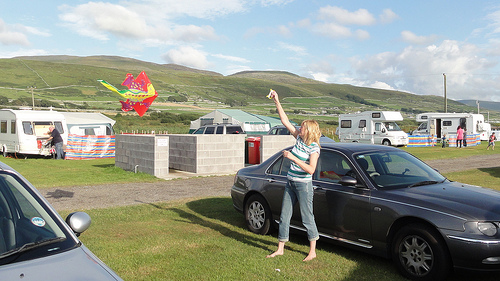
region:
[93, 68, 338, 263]
A WOMAN FLYING A KITE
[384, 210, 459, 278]
A FRONT CARS TIRE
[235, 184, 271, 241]
A REAR CARS TIRE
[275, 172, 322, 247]
A PAIR OF BLUE JEANS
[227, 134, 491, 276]
A BLACK CAR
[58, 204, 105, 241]
A SIDE VIEW MIRROR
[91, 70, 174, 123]
A KITE FLYING IN THE AIR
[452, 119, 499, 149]
TWO PEOPLE IN THE BACKGROUND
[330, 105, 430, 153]
A WHITE CAMPER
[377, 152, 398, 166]
A REAR VIEW MIRROR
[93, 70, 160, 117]
A multicolored flying kite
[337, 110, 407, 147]
A white drivable camper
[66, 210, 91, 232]
Side view mirror of a silver car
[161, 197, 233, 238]
Shadows on the grassy ground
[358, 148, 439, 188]
Windshield of a car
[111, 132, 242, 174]
A partial concrete block wall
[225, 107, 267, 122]
A green roof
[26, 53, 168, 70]
Grassy green mountain top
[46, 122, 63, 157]
Person in a black shirt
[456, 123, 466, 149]
Lady in a pink shirt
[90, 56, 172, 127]
a kite in the air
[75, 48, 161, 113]
a kite flying low in the air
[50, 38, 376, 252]
a woman flying a kite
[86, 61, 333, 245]
a woman holding a kite string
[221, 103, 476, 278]
a woman standing next to car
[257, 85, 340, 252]
a woman with blonde hair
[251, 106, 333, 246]
a woman wearing a striped shirt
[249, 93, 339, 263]
a woman wearing pants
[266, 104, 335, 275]
a woman wearing jeans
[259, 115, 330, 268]
a woman wearing blue jeans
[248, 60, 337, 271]
bare foot blind woman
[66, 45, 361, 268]
bare foot blonde woman flying kite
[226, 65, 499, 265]
black car beside woman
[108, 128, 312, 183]
unpainted block structure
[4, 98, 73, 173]
black shirted man by trailer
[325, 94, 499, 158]
two white motor homes parked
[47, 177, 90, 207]
kites shadow on dirt road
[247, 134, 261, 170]
red recycling bin in block structure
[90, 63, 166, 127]
multi colored airbourne kite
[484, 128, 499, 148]
kid playing around trailer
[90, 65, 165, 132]
The kite is rainbow colored.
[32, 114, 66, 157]
The man is reaching for an item.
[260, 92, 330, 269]
The lady is wearing no shoes.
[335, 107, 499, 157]
RV campers are in the background.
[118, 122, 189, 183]
A gray brick wall has no ceiling.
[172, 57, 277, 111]
A grassy landscape is in the back drop.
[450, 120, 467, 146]
The person is wearing a pink shirt.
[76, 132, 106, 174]
A red and blue stripe fence made from plastic is creating a barrier.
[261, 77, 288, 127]
The kite string is white.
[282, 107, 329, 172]
The woman has blond hair.